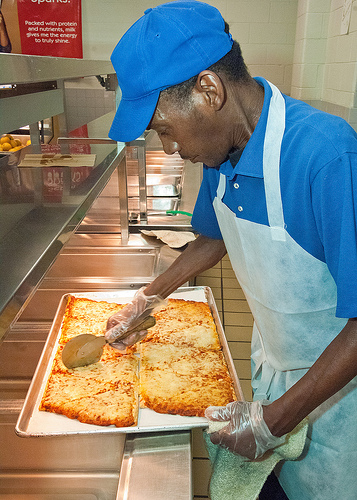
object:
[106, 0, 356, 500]
man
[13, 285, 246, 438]
tray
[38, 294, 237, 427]
pizza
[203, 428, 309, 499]
towel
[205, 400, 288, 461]
glove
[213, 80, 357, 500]
apron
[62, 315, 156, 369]
cutter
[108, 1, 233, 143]
hat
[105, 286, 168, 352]
glove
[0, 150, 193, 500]
counter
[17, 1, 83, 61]
sign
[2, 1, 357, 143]
wall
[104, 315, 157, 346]
handle